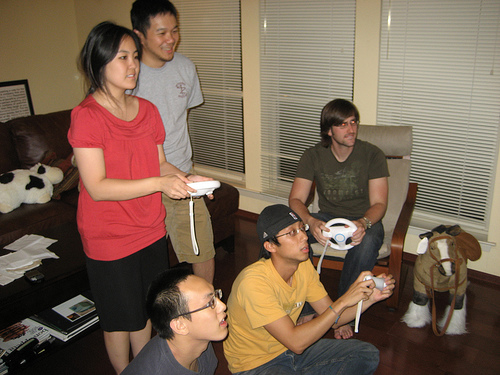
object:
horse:
[400, 225, 467, 335]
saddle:
[453, 227, 480, 262]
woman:
[66, 22, 216, 374]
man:
[130, 1, 215, 287]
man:
[282, 99, 388, 305]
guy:
[220, 204, 395, 375]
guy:
[124, 263, 231, 375]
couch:
[1, 106, 243, 260]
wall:
[2, 1, 86, 106]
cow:
[0, 162, 64, 214]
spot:
[25, 172, 45, 191]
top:
[65, 96, 167, 263]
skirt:
[84, 236, 171, 333]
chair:
[304, 123, 419, 313]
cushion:
[311, 124, 413, 259]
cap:
[258, 202, 302, 243]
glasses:
[171, 287, 225, 319]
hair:
[146, 265, 192, 339]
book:
[27, 292, 100, 342]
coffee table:
[1, 218, 106, 373]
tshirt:
[220, 256, 329, 373]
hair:
[319, 99, 359, 137]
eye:
[348, 118, 355, 124]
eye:
[338, 119, 349, 128]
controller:
[178, 179, 220, 255]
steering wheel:
[314, 216, 357, 274]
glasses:
[269, 223, 309, 240]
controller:
[353, 276, 389, 333]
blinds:
[259, 0, 355, 214]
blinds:
[171, 0, 243, 182]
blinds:
[377, 1, 498, 243]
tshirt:
[124, 49, 206, 173]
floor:
[34, 208, 498, 375]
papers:
[0, 232, 60, 286]